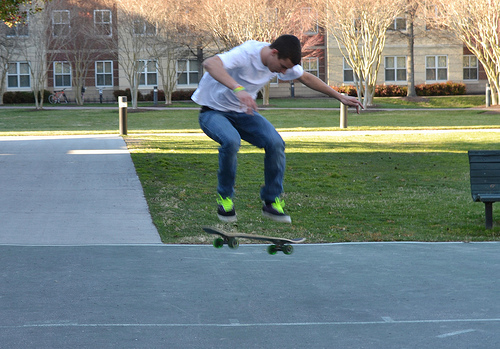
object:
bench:
[467, 150, 499, 230]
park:
[0, 0, 500, 349]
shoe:
[260, 196, 292, 224]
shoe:
[215, 193, 237, 221]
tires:
[212, 237, 239, 250]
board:
[202, 227, 307, 256]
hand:
[341, 96, 365, 115]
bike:
[48, 88, 69, 105]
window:
[424, 54, 451, 83]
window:
[383, 54, 407, 82]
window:
[134, 59, 158, 87]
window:
[5, 61, 31, 90]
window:
[175, 58, 203, 87]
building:
[0, 0, 496, 103]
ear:
[270, 49, 278, 57]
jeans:
[198, 106, 287, 201]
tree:
[414, 0, 499, 106]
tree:
[302, 0, 417, 113]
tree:
[195, 0, 325, 106]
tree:
[75, 0, 189, 109]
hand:
[236, 90, 258, 116]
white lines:
[0, 318, 500, 329]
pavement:
[0, 239, 500, 349]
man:
[190, 34, 365, 224]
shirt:
[190, 40, 304, 113]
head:
[266, 34, 302, 75]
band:
[232, 85, 246, 94]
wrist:
[333, 92, 343, 101]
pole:
[118, 96, 128, 136]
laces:
[216, 193, 235, 213]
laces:
[271, 196, 286, 213]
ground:
[2, 93, 495, 347]